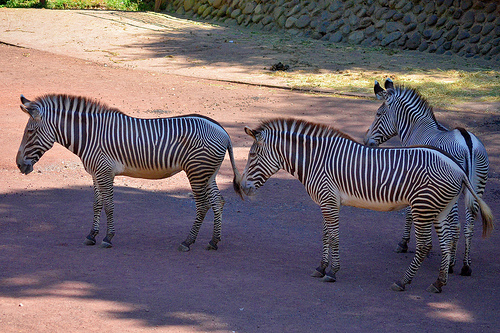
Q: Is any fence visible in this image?
A: No, there are no fences.